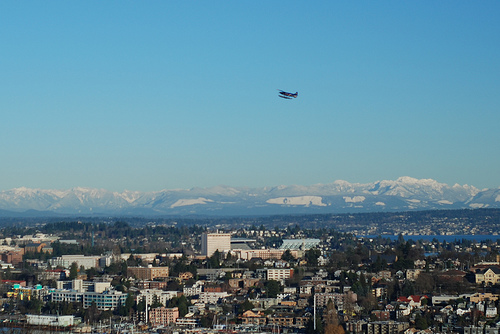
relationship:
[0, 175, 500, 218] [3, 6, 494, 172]
mountains under sky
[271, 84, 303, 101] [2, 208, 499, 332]
airplane over city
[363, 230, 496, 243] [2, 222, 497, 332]
water in city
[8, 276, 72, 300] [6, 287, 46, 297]
mounds on top of building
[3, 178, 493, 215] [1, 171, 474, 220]
snow covered tops of mountains